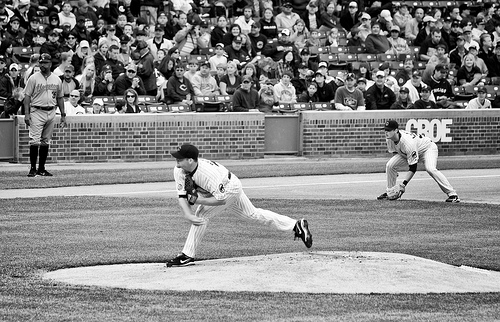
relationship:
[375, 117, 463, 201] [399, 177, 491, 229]
baseman at third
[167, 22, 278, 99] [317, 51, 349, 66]
children in seats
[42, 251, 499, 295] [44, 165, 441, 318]
pitcher mount on field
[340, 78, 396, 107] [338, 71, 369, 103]
head of man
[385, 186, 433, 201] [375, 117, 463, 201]
mitt on baseman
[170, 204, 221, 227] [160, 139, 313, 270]
arm of pitcher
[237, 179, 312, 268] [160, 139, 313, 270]
leg of pitcher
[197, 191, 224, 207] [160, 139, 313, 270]
belt on pitcher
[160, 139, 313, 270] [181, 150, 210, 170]
pitcher has ear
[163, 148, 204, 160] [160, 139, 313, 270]
cap on pitcher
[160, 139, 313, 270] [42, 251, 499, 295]
pitcher on pitcher mount